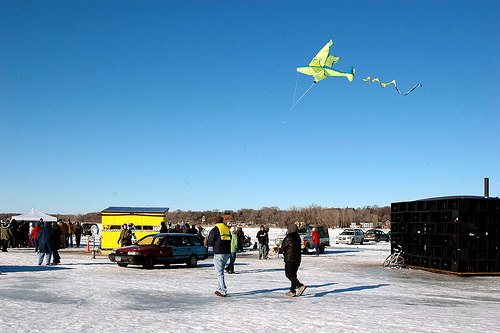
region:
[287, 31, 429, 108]
kite in the sky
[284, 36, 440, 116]
kite shaped like an airplane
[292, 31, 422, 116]
bright green kite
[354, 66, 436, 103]
thin, curly kite tail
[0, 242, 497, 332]
snow on the ground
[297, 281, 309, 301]
heel is lifted of the ground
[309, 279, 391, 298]
shadow on the ground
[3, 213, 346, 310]
people walking on the snow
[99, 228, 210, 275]
red and white vehicle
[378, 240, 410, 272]
bike that is leaning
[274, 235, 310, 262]
the jacket is black in color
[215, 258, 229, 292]
the trouser is faded blue in color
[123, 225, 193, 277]
the car is red and light blue in color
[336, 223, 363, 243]
the car is white in color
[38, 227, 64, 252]
the jackets are navy blue in color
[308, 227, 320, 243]
the jacket is red in color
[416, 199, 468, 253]
the box is black in color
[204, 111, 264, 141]
the sky is clear blue in color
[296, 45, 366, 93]
the kite is light green in color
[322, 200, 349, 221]
the plants are dried brown in color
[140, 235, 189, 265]
the car is maroon in color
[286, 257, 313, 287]
the pants ar black in color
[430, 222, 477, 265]
the block is black in color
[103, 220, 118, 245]
the wall is yellow in color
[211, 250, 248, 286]
the pants are faded blue in color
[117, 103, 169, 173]
the sky is clera light blue in color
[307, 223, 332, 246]
the jacket is red in color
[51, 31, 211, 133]
this is the sky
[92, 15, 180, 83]
the sky is blue in color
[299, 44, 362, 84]
this is the kite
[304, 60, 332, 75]
the kite is yellow in color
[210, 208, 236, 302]
this is a man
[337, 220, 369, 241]
this is a car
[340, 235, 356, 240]
the car is white in color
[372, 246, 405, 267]
this is a bicycle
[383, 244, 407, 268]
the bicycle is parked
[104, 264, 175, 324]
this is the ground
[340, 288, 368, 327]
part of a ground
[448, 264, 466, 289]
edge of a line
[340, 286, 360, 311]
part of a shade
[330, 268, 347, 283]
part of a ground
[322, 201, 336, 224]
green leaves on the tree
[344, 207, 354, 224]
green leaves on the tree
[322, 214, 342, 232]
green leaves on the tree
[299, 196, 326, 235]
green leaves on the tree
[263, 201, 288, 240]
green leaves on the tree